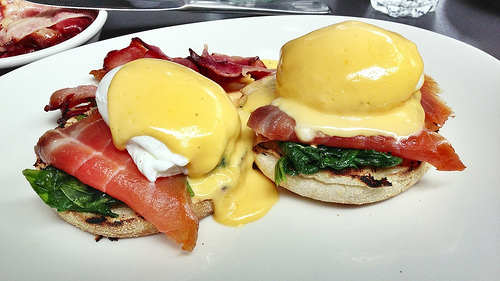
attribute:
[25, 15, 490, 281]
plate — white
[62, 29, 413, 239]
sandwich — open-face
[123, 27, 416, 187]
sauce — yellow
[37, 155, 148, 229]
vegetable — green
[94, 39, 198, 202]
food — white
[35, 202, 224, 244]
muffin — toasted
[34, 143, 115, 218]
spinach — green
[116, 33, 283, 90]
bacon — cooked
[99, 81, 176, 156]
egg — folded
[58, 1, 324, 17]
knife — silver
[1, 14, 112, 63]
dish — white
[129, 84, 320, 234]
cheese — melted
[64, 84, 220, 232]
meat — sliced